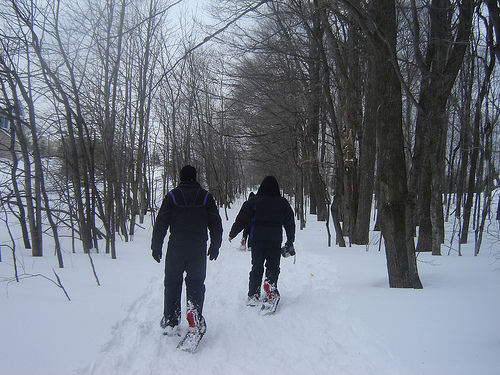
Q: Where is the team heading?
A: Into the woods.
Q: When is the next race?
A: Next Saturday.